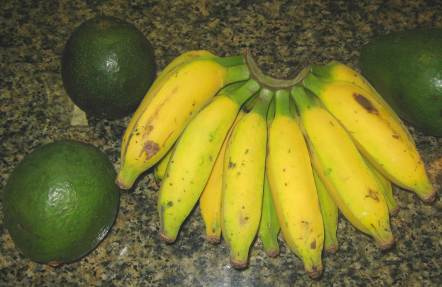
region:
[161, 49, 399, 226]
A bunch of bananas.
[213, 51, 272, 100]
The stems are green.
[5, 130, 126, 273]
The avocado is green.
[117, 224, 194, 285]
The fruits are on a counter.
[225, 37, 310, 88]
The core of the banana stems.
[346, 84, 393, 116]
Dark spot on the banana.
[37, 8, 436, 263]
Three avocados in the picture.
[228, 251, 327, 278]
The bottom of the bananas are brown.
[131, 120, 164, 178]
Large spot on the banana.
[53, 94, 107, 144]
Light reflection on the table.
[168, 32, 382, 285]
A bunch of bananas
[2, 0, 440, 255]
Bananas and Avocados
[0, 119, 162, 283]
Just one avocado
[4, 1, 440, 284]
Fruit on a granite countertop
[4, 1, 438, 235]
A red brown kitchen countertop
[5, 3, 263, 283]
Two unripe avocados and a banana bunch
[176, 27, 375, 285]
Small sized bananas in a bunch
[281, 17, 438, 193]
Ripe bananas and an unripe avocado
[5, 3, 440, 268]
Tropical fruit on a kitchen countertop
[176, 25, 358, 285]
These bananas are ripe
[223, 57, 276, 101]
The stem is green.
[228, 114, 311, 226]
The banana is yellow.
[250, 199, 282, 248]
The banana is green.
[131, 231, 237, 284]
The counter is marble.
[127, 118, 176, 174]
Dark spot on the banana.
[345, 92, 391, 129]
Bruise on the banana.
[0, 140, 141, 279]
The avocado is green.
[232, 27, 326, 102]
The core is brown.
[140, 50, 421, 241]
A bundle of bananas.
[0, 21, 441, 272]
Fruit on a counter.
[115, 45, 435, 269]
a bushel of yellow fruit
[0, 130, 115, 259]
A round green fruit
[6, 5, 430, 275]
two kinds of fruit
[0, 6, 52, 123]
a granite counter top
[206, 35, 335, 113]
green tops of fruit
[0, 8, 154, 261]
two green fruits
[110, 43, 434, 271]
eleven pieces of yellow fruit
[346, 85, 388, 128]
brown bruise on the fruit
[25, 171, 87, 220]
white glare on fruit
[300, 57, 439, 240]
two yellow and green fruits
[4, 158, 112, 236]
this is avocado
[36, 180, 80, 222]
the avocado is green in color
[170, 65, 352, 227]
this is a bunch of banana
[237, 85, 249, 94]
the stalk is green in color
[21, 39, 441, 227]
the avocado are three in number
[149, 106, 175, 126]
the banana is yellow in color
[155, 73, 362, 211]
the banana are thirteen in number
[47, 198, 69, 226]
the banana has patches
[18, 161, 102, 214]
the avocado is round in shape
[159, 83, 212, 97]
the banana is curved